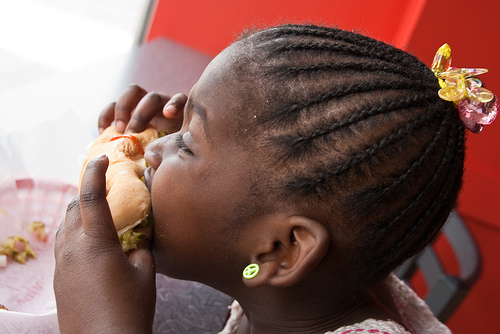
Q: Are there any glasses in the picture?
A: No, there are no glasses.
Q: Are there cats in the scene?
A: No, there are no cats.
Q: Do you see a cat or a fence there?
A: No, there are no cats or fences.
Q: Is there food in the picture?
A: Yes, there is food.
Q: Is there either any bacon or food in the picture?
A: Yes, there is food.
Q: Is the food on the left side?
A: Yes, the food is on the left of the image.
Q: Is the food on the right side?
A: No, the food is on the left of the image.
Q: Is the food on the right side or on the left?
A: The food is on the left of the image.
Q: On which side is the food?
A: The food is on the left of the image.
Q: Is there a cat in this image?
A: No, there are no cats.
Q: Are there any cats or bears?
A: No, there are no cats or bears.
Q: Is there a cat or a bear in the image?
A: No, there are no cats or bears.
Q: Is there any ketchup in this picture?
A: Yes, there is ketchup.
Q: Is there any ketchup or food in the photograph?
A: Yes, there is ketchup.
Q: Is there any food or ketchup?
A: Yes, there is ketchup.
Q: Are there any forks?
A: No, there are no forks.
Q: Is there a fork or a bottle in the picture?
A: No, there are no forks or bottles.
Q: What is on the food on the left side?
A: The ketchup is on the food.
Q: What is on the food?
A: The ketchup is on the food.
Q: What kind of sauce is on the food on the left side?
A: The sauce is ketchup.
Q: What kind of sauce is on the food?
A: The sauce is ketchup.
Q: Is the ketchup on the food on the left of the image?
A: Yes, the ketchup is on the food.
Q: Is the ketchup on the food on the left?
A: Yes, the ketchup is on the food.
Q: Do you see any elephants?
A: No, there are no elephants.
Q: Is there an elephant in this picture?
A: No, there are no elephants.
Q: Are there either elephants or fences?
A: No, there are no elephants or fences.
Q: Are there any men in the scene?
A: No, there are no men.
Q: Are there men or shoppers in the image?
A: No, there are no men or shoppers.